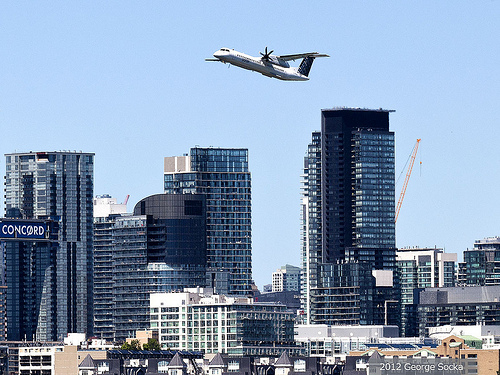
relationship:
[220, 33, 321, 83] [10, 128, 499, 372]
plane over city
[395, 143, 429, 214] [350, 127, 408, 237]
crane behind building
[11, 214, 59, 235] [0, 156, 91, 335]
name on building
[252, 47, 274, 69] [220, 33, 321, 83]
propeller on plane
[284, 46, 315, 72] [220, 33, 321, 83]
stabilizer on plane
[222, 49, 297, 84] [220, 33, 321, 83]
windows on plane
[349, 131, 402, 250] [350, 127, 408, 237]
windows on building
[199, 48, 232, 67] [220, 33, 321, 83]
nose on plane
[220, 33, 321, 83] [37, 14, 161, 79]
plane in sky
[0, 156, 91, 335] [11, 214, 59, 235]
building has name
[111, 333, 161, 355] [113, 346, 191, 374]
trees on building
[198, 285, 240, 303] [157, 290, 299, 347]
chairs on building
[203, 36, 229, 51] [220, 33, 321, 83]
cockpit on plane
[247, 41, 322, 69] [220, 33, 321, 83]
wings on plane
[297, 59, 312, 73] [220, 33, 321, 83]
tail on plane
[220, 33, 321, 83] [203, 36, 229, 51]
plane has cockpit